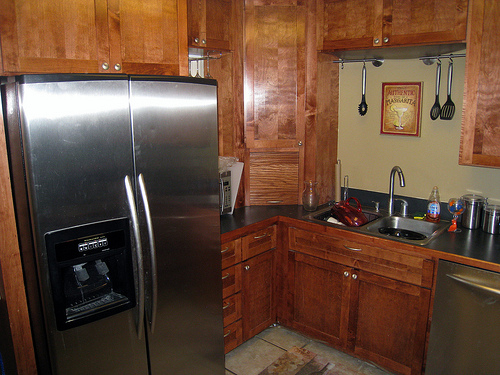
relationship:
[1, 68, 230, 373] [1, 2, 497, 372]
appliance in kitchen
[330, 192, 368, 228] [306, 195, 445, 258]
pitcher in sink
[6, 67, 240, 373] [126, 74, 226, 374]
refrigerator with door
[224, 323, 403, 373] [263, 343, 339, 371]
tiles under rug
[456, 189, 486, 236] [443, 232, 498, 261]
canister on counter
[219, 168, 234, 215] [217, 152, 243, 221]
panel of microwave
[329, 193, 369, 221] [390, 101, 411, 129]
border of trophy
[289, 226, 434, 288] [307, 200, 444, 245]
drawer under sink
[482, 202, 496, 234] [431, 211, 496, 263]
canister on counter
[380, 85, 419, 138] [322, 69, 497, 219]
sign on wall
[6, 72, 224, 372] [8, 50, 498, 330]
refrigerator in kitchen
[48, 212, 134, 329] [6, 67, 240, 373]
dispenser on refrigerator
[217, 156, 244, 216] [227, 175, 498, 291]
microwave on counter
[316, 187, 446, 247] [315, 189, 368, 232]
sink of dishes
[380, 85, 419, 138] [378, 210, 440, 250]
sign over sink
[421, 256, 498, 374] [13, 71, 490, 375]
dishwasher in kitchen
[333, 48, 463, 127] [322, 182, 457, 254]
utensils above sink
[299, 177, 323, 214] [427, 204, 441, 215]
vase next to sink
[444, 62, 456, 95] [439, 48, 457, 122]
handle on utensils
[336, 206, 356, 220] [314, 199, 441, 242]
dishes on sink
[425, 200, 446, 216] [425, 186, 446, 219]
label on label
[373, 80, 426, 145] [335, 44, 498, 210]
picture hanging on wall